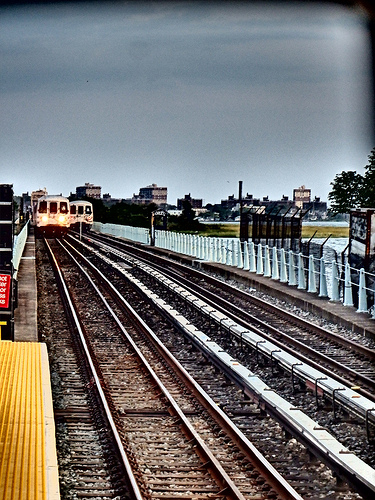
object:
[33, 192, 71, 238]
train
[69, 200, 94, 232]
train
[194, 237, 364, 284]
fence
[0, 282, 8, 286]
lettering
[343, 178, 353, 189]
leaves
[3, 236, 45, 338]
workers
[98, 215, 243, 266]
rail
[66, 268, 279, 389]
bed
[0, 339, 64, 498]
overhang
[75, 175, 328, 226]
buildings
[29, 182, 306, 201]
background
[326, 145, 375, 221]
tree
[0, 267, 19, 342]
bench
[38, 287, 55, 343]
grate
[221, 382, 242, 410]
rocks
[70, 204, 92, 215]
window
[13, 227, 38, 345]
platform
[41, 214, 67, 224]
headlights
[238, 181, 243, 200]
chimney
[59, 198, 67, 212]
visible operator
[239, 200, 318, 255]
black fence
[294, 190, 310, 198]
billboard sign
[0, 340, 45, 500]
yellow coloring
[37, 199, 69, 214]
train windows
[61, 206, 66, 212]
person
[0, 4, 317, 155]
blue sky